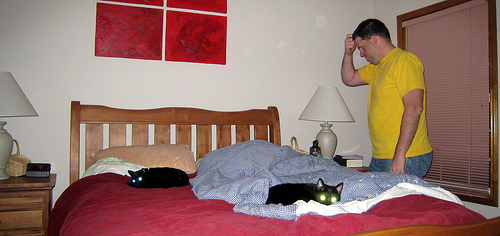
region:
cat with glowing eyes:
[258, 169, 360, 214]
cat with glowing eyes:
[117, 159, 194, 193]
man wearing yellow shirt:
[334, 16, 440, 158]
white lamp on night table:
[291, 68, 356, 170]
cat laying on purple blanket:
[188, 139, 402, 225]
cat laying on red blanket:
[102, 159, 207, 206]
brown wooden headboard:
[57, 74, 297, 178]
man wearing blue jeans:
[337, 13, 440, 188]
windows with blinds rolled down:
[392, 7, 497, 201]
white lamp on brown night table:
[0, 64, 60, 229]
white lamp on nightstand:
[0, 63, 48, 194]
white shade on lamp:
[1, 66, 40, 144]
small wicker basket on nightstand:
[7, 137, 32, 187]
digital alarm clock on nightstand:
[22, 157, 57, 190]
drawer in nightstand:
[4, 197, 47, 231]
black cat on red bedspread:
[122, 165, 192, 197]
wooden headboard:
[65, 96, 295, 171]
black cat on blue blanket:
[255, 180, 371, 220]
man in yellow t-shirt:
[335, 13, 440, 199]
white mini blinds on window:
[421, 17, 488, 201]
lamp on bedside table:
[298, 76, 361, 176]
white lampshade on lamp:
[292, 77, 355, 135]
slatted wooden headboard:
[65, 91, 291, 179]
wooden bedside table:
[3, 176, 55, 231]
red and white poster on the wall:
[85, 7, 251, 83]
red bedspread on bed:
[71, 187, 192, 234]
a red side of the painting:
[196, 24, 227, 71]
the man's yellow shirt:
[376, 83, 391, 100]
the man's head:
[348, 22, 394, 67]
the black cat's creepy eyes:
[313, 182, 341, 198]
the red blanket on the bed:
[116, 204, 153, 229]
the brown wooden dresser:
[23, 192, 45, 212]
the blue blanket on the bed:
[246, 147, 267, 170]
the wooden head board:
[180, 115, 212, 133]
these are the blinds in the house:
[459, 72, 488, 109]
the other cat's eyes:
[128, 165, 150, 182]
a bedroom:
[4, 5, 494, 230]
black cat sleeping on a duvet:
[256, 171, 358, 222]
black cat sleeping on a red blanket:
[107, 162, 200, 197]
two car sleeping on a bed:
[119, 150, 365, 233]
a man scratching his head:
[325, 16, 432, 89]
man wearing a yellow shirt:
[351, 50, 448, 160]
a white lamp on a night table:
[288, 72, 354, 157]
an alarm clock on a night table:
[26, 157, 53, 182]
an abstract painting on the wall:
[81, 2, 241, 77]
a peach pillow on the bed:
[89, 138, 209, 170]